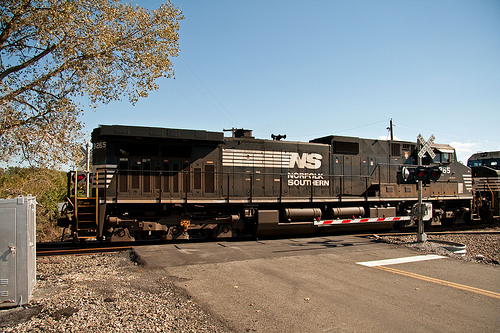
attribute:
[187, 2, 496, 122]
sky — blue, clear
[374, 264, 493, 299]
lines — yellow, double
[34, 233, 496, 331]
ground — rocky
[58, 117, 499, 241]
train — moving, black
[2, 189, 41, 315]
box — gray, electrical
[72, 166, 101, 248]
ladder — yellow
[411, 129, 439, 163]
sign — x, black, white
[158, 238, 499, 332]
street — black, grey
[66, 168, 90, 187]
lights — red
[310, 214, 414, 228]
strip — red, white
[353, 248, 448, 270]
line — thick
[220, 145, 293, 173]
stripes — white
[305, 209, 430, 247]
gate — down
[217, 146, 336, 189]
logo — white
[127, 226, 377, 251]
ramp — asphalt